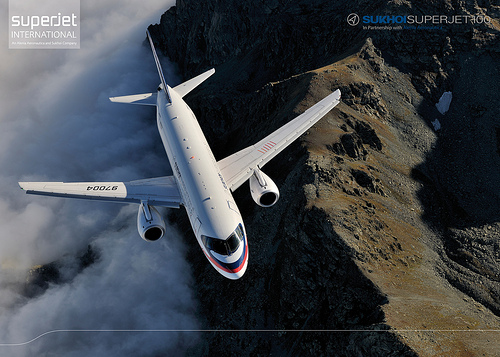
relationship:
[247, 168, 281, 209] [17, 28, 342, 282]
engine part of airplane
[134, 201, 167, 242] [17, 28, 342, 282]
engine part of airplane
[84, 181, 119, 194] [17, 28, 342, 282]
97004 painted on airplane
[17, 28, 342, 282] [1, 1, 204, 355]
airplane soaring in sky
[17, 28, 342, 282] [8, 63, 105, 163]
airplane over clouds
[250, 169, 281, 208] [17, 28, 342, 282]
engine beneath airplane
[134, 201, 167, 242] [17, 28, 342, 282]
engine beneath airplane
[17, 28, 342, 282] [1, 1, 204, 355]
airplane flying through sky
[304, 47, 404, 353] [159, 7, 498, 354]
peak at top of mountain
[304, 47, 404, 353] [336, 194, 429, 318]
peak covered with dirt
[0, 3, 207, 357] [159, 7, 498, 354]
clouds on side of mountain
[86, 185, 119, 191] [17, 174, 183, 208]
numbers painted on wing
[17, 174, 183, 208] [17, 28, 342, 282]
wing part of airplane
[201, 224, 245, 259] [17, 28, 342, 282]
windshield on front of airplane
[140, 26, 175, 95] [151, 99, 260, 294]
tail part of plane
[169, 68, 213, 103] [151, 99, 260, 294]
tail fin part of plane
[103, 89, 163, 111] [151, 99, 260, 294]
tail fin part of plane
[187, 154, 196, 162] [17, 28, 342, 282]
light on top of airplane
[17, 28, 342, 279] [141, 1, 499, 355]
airplane flying over mountains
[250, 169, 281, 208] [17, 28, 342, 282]
engine underneath airplane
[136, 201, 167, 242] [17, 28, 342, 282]
engine underneath airplane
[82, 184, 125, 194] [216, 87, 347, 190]
numbers on wing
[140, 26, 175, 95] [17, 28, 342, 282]
tail on airplane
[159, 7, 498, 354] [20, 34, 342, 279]
mountain under plane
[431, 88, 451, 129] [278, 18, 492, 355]
snow on moutain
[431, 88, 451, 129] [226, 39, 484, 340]
snow on mountain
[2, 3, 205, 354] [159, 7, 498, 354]
clouds on mountain